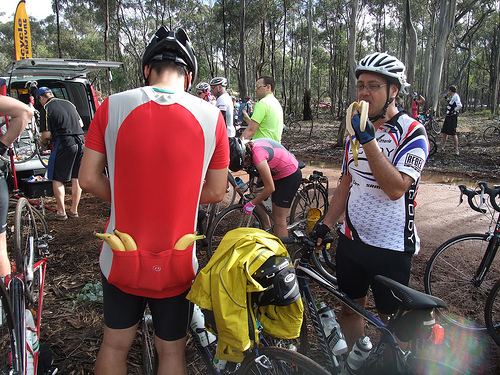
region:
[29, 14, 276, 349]
a man with three bananas in his back pocket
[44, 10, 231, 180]
a man wearing a black helmet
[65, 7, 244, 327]
a man wearing a red and white shirt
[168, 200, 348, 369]
a yellow jacket on bike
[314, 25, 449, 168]
a man wearing a white helmet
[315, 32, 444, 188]
a man eating a banana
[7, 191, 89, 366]
a bike turned upside down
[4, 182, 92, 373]
a bike upside down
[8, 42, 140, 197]
a vehicle with back door open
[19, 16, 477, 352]
group of bicyclist standing around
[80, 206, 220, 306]
pockets full of bananas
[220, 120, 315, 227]
a woman working on her bike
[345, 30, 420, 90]
a bike helmet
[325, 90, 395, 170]
unpeeled banana being eaten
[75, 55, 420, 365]
before the big road race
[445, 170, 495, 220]
handbreaks on a bike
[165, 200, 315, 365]
yellow slicker in case of rain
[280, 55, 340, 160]
woods at the bike race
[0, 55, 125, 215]
working out of the hatchback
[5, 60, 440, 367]
a group of riders prepare themselves and their bikes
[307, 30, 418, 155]
a man eating banana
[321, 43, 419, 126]
a man wearing a white helmet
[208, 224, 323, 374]
a yellow rain jacket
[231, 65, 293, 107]
a man wearing glasses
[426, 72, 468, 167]
a man wearing black shorts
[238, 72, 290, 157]
a man wearing a green shirt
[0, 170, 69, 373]
a red bike turned upside down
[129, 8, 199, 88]
a man wearing a black helmet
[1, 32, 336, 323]
several people standing around in the forrest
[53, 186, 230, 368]
Bananas in back pockets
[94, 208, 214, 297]
One empty pocket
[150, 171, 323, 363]
Banana yello jacket on bike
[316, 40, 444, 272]
Biker eating a banana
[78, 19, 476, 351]
Getting ready to ride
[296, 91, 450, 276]
Red, black, blue and white shirt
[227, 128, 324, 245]
Making an adjustment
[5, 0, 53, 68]
Yellow sign with blue lettering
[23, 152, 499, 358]
Dirt trails abound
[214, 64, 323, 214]
Easter egg green and pink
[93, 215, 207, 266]
Three yellow bananas in pocket.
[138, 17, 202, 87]
A black safety helmet.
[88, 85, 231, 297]
A red and white shirt.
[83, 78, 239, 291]
A short sleeve shirt.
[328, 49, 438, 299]
Man eating a banana.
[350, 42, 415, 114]
White safety helmet.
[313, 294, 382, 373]
Two water bottles.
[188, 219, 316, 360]
A yellow jacket.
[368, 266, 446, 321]
Black seat on bicycle.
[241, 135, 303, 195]
A pink short sleeve shirt.